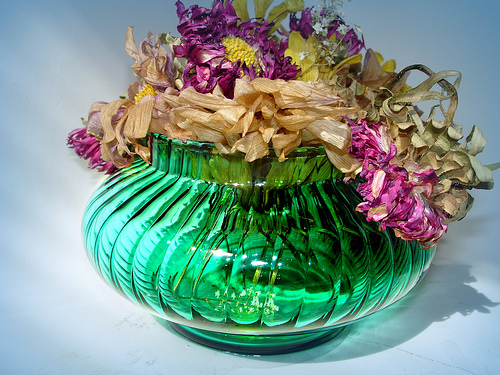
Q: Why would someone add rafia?
A: For texture.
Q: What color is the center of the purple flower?
A: Yellow.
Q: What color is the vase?
A: Green.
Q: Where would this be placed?
A: On a table.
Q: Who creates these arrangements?
A: Florists.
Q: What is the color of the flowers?
A: Purple and yellow.